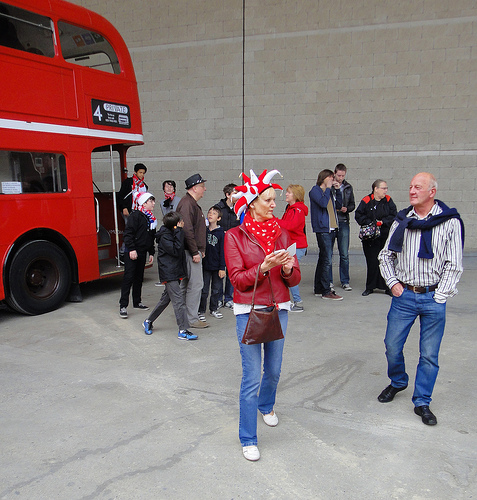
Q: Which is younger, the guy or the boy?
A: The boy is younger than the guy.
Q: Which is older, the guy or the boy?
A: The guy is older than the boy.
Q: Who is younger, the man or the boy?
A: The boy is younger than the man.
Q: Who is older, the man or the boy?
A: The man is older than the boy.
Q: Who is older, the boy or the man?
A: The man is older than the boy.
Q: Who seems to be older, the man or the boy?
A: The man is older than the boy.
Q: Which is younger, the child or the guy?
A: The child is younger than the guy.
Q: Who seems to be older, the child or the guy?
A: The guy is older than the child.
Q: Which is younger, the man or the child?
A: The child is younger than the man.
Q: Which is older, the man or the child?
A: The man is older than the child.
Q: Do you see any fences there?
A: No, there are no fences.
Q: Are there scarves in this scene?
A: Yes, there is a scarf.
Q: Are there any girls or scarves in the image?
A: Yes, there is a scarf.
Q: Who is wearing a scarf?
A: The guy is wearing a scarf.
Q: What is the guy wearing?
A: The guy is wearing a scarf.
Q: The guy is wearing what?
A: The guy is wearing a scarf.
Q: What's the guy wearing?
A: The guy is wearing a scarf.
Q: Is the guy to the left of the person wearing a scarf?
A: Yes, the guy is wearing a scarf.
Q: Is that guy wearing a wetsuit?
A: No, the guy is wearing a scarf.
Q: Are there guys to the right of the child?
A: Yes, there is a guy to the right of the child.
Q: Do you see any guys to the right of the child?
A: Yes, there is a guy to the right of the child.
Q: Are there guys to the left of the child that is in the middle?
A: No, the guy is to the right of the child.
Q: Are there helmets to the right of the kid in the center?
A: No, there is a guy to the right of the child.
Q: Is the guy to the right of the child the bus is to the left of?
A: Yes, the guy is to the right of the kid.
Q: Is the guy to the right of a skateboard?
A: No, the guy is to the right of the kid.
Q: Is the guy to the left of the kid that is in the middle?
A: No, the guy is to the right of the kid.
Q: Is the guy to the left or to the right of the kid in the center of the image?
A: The guy is to the right of the child.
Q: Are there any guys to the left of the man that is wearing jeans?
A: Yes, there is a guy to the left of the man.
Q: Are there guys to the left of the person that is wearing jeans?
A: Yes, there is a guy to the left of the man.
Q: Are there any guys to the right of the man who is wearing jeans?
A: No, the guy is to the left of the man.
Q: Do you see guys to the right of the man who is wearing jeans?
A: No, the guy is to the left of the man.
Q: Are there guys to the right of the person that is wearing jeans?
A: No, the guy is to the left of the man.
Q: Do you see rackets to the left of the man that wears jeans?
A: No, there is a guy to the left of the man.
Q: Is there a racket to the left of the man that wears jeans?
A: No, there is a guy to the left of the man.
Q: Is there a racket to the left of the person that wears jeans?
A: No, there is a guy to the left of the man.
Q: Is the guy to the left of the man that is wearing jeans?
A: Yes, the guy is to the left of the man.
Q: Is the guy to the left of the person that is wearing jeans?
A: Yes, the guy is to the left of the man.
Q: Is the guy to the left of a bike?
A: No, the guy is to the left of the man.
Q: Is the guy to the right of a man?
A: No, the guy is to the left of a man.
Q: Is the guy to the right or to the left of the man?
A: The guy is to the left of the man.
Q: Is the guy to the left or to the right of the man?
A: The guy is to the left of the man.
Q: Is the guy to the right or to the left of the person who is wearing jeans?
A: The guy is to the left of the man.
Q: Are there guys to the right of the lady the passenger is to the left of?
A: Yes, there is a guy to the right of the lady.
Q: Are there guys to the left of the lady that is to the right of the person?
A: No, the guy is to the right of the lady.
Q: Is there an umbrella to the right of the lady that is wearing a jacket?
A: No, there is a guy to the right of the lady.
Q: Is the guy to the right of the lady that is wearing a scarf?
A: Yes, the guy is to the right of the lady.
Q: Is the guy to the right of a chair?
A: No, the guy is to the right of the lady.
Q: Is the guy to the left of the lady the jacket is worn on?
A: No, the guy is to the right of the lady.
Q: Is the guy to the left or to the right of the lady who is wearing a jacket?
A: The guy is to the right of the lady.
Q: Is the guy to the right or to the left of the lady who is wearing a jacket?
A: The guy is to the right of the lady.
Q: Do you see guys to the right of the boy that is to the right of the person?
A: Yes, there is a guy to the right of the boy.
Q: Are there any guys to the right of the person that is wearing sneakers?
A: Yes, there is a guy to the right of the boy.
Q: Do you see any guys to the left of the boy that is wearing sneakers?
A: No, the guy is to the right of the boy.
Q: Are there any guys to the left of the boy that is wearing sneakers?
A: No, the guy is to the right of the boy.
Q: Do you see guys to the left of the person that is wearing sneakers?
A: No, the guy is to the right of the boy.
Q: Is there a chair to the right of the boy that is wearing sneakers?
A: No, there is a guy to the right of the boy.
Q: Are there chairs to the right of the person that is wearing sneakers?
A: No, there is a guy to the right of the boy.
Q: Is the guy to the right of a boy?
A: Yes, the guy is to the right of a boy.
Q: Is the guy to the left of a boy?
A: No, the guy is to the right of a boy.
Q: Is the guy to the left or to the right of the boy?
A: The guy is to the right of the boy.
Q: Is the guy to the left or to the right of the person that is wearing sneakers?
A: The guy is to the right of the boy.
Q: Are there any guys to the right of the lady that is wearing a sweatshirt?
A: Yes, there is a guy to the right of the lady.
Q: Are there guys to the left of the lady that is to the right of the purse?
A: No, the guy is to the right of the lady.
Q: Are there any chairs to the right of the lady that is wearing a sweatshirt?
A: No, there is a guy to the right of the lady.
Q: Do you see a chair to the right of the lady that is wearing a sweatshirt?
A: No, there is a guy to the right of the lady.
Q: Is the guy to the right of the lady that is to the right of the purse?
A: Yes, the guy is to the right of the lady.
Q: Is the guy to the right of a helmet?
A: No, the guy is to the right of the lady.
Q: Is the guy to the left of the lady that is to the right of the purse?
A: No, the guy is to the right of the lady.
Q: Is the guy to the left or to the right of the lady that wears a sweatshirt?
A: The guy is to the right of the lady.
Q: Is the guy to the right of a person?
A: No, the guy is to the left of a person.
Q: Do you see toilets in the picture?
A: No, there are no toilets.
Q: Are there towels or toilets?
A: No, there are no toilets or towels.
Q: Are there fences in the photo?
A: No, there are no fences.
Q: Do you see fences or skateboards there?
A: No, there are no fences or skateboards.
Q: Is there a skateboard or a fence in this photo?
A: No, there are no fences or skateboards.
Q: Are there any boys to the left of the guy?
A: Yes, there is a boy to the left of the guy.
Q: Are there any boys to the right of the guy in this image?
A: No, the boy is to the left of the guy.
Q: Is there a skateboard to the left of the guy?
A: No, there is a boy to the left of the guy.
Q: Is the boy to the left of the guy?
A: Yes, the boy is to the left of the guy.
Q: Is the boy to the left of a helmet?
A: No, the boy is to the left of the guy.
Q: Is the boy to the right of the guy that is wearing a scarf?
A: No, the boy is to the left of the guy.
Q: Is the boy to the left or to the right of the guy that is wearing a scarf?
A: The boy is to the left of the guy.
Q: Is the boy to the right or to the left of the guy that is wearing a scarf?
A: The boy is to the left of the guy.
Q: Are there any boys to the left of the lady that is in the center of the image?
A: Yes, there is a boy to the left of the lady.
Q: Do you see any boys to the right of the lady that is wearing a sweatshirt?
A: No, the boy is to the left of the lady.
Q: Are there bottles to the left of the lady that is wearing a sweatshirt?
A: No, there is a boy to the left of the lady.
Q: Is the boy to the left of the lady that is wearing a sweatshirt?
A: Yes, the boy is to the left of the lady.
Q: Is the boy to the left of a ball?
A: No, the boy is to the left of the lady.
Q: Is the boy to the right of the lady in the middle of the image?
A: No, the boy is to the left of the lady.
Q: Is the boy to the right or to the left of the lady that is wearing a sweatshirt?
A: The boy is to the left of the lady.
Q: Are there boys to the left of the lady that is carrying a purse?
A: Yes, there is a boy to the left of the lady.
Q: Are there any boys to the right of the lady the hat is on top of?
A: No, the boy is to the left of the lady.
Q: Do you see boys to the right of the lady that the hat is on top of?
A: No, the boy is to the left of the lady.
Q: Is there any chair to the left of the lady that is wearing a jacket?
A: No, there is a boy to the left of the lady.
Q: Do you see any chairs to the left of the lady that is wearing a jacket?
A: No, there is a boy to the left of the lady.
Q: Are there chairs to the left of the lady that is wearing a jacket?
A: No, there is a boy to the left of the lady.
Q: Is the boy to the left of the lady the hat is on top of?
A: Yes, the boy is to the left of the lady.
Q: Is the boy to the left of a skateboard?
A: No, the boy is to the left of the lady.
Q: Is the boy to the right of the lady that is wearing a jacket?
A: No, the boy is to the left of the lady.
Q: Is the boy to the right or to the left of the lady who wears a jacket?
A: The boy is to the left of the lady.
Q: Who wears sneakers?
A: The boy wears sneakers.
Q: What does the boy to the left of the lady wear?
A: The boy wears sneakers.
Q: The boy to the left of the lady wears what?
A: The boy wears sneakers.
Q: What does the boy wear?
A: The boy wears sneakers.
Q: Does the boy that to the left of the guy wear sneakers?
A: Yes, the boy wears sneakers.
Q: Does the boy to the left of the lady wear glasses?
A: No, the boy wears sneakers.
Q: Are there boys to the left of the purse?
A: Yes, there is a boy to the left of the purse.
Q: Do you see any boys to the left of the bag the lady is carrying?
A: Yes, there is a boy to the left of the purse.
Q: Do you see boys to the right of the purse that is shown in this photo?
A: No, the boy is to the left of the purse.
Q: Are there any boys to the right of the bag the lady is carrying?
A: No, the boy is to the left of the purse.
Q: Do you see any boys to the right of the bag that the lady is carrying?
A: No, the boy is to the left of the purse.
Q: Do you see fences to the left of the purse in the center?
A: No, there is a boy to the left of the purse.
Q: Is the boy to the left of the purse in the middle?
A: Yes, the boy is to the left of the purse.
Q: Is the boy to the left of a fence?
A: No, the boy is to the left of the purse.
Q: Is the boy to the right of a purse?
A: No, the boy is to the left of a purse.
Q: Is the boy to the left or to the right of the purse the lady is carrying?
A: The boy is to the left of the purse.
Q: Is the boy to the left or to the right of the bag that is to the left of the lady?
A: The boy is to the left of the purse.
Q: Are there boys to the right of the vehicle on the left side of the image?
A: Yes, there is a boy to the right of the bus.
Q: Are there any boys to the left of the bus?
A: No, the boy is to the right of the bus.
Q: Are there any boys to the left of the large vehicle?
A: No, the boy is to the right of the bus.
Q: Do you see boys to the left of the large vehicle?
A: No, the boy is to the right of the bus.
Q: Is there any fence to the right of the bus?
A: No, there is a boy to the right of the bus.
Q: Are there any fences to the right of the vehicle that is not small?
A: No, there is a boy to the right of the bus.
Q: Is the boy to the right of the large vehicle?
A: Yes, the boy is to the right of the bus.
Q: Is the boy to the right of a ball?
A: No, the boy is to the right of the bus.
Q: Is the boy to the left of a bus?
A: No, the boy is to the right of a bus.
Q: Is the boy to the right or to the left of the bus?
A: The boy is to the right of the bus.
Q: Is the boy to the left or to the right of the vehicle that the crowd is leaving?
A: The boy is to the right of the bus.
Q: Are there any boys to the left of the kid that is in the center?
A: Yes, there is a boy to the left of the kid.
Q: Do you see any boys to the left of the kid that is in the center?
A: Yes, there is a boy to the left of the kid.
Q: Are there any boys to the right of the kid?
A: No, the boy is to the left of the kid.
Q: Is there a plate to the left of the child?
A: No, there is a boy to the left of the child.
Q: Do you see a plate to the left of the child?
A: No, there is a boy to the left of the child.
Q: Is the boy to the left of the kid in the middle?
A: Yes, the boy is to the left of the kid.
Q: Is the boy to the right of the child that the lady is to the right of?
A: No, the boy is to the left of the kid.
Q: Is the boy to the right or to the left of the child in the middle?
A: The boy is to the left of the child.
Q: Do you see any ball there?
A: No, there are no balls.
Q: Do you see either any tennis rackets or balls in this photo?
A: No, there are no balls or tennis rackets.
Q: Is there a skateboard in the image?
A: No, there are no skateboards.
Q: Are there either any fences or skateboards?
A: No, there are no skateboards or fences.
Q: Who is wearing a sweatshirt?
A: The lady is wearing a sweatshirt.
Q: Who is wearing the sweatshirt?
A: The lady is wearing a sweatshirt.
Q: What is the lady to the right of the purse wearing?
A: The lady is wearing a sweatshirt.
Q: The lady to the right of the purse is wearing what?
A: The lady is wearing a sweatshirt.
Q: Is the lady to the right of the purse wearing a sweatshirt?
A: Yes, the lady is wearing a sweatshirt.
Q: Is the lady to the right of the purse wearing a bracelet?
A: No, the lady is wearing a sweatshirt.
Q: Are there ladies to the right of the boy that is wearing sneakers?
A: Yes, there is a lady to the right of the boy.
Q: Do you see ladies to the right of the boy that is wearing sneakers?
A: Yes, there is a lady to the right of the boy.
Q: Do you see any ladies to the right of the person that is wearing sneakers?
A: Yes, there is a lady to the right of the boy.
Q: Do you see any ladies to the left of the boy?
A: No, the lady is to the right of the boy.